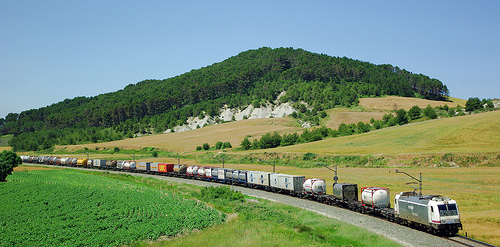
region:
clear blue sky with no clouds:
[1, 0, 499, 116]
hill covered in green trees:
[1, 45, 471, 120]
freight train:
[20, 153, 462, 236]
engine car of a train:
[394, 190, 461, 237]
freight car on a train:
[268, 172, 304, 197]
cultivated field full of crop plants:
[0, 168, 225, 245]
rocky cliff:
[164, 97, 312, 132]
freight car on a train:
[247, 170, 274, 192]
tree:
[0, 152, 22, 182]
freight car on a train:
[157, 162, 174, 174]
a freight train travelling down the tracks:
[13, 102, 462, 237]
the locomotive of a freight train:
[395, 184, 467, 236]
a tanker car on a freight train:
[356, 181, 392, 212]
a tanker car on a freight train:
[296, 175, 328, 196]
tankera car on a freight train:
[173, 163, 208, 180]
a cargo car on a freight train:
[270, 170, 301, 195]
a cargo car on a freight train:
[245, 167, 270, 189]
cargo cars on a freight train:
[3, 144, 385, 225]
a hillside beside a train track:
[16, 40, 466, 177]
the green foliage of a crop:
[1, 163, 211, 244]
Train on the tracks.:
[14, 153, 467, 232]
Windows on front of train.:
[435, 198, 456, 220]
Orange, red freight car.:
[156, 159, 173, 174]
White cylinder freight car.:
[357, 182, 389, 209]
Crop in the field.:
[1, 163, 222, 244]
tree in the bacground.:
[1, 145, 23, 182]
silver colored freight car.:
[267, 168, 306, 194]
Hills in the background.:
[1, 92, 498, 152]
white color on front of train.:
[423, 193, 463, 225]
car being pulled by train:
[357, 187, 389, 216]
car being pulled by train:
[323, 180, 356, 208]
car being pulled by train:
[296, 178, 331, 202]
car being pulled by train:
[267, 169, 302, 194]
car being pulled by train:
[245, 168, 270, 187]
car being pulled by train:
[225, 168, 245, 182]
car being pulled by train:
[200, 166, 223, 182]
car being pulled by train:
[183, 164, 204, 176]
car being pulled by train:
[149, 163, 169, 173]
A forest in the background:
[127, 69, 197, 119]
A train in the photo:
[209, 172, 329, 210]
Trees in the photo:
[262, 54, 312, 93]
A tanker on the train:
[353, 182, 388, 208]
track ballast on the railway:
[352, 208, 399, 231]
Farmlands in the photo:
[82, 189, 113, 239]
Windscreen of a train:
[440, 202, 459, 218]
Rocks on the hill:
[228, 94, 283, 119]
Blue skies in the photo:
[348, 21, 412, 51]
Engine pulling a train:
[393, 190, 460, 235]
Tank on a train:
[359, 184, 389, 209]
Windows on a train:
[437, 201, 455, 211]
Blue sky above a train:
[2, 1, 499, 120]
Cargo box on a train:
[269, 171, 306, 190]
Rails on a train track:
[446, 233, 498, 245]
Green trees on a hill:
[0, 45, 451, 148]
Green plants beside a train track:
[190, 185, 248, 204]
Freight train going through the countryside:
[20, 151, 465, 236]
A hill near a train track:
[136, 109, 498, 166]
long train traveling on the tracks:
[23, 146, 465, 239]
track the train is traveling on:
[38, 160, 485, 244]